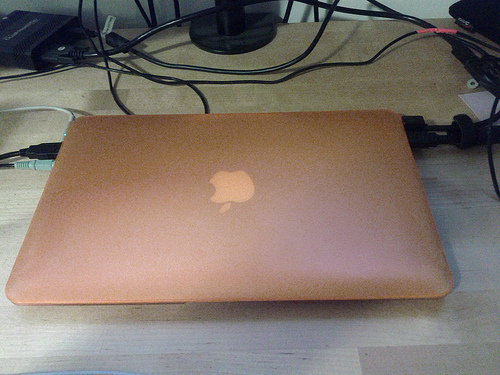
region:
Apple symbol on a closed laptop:
[203, 164, 259, 223]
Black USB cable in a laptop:
[18, 137, 73, 158]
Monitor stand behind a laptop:
[183, 0, 280, 55]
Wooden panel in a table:
[293, 317, 493, 373]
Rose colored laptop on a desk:
[4, 100, 456, 310]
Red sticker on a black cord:
[411, 22, 465, 39]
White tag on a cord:
[98, 14, 119, 39]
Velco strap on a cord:
[452, 112, 477, 150]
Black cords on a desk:
[142, 45, 359, 96]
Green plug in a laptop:
[13, 155, 61, 172]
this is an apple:
[199, 160, 261, 204]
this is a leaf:
[212, 197, 234, 216]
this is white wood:
[318, 330, 365, 355]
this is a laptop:
[3, 105, 476, 326]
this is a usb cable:
[11, 135, 70, 164]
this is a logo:
[206, 170, 265, 214]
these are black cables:
[126, 56, 251, 113]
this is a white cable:
[6, 95, 75, 134]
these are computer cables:
[403, 91, 498, 161]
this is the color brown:
[302, 204, 329, 233]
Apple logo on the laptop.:
[199, 150, 372, 240]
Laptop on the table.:
[38, 105, 440, 340]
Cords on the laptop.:
[383, 95, 498, 155]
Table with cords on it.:
[84, 47, 496, 306]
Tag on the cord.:
[85, 24, 128, 37]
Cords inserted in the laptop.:
[8, 109, 90, 191]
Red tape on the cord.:
[395, 13, 495, 50]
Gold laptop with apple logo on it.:
[44, 107, 299, 370]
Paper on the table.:
[408, 51, 498, 146]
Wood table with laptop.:
[45, 8, 460, 373]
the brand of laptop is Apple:
[0, 92, 470, 320]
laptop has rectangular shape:
[0, 101, 465, 312]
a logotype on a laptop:
[196, 157, 264, 221]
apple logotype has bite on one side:
[194, 163, 260, 220]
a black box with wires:
[5, 8, 95, 77]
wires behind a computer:
[87, 30, 427, 105]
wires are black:
[103, 44, 425, 96]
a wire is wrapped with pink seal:
[394, 16, 467, 51]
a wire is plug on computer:
[9, 146, 56, 176]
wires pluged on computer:
[7, 103, 95, 175]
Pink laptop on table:
[52, 110, 418, 336]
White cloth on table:
[225, 317, 385, 352]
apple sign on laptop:
[197, 151, 264, 224]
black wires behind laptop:
[88, 70, 219, 108]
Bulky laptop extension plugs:
[404, 107, 481, 163]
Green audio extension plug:
[5, 156, 55, 180]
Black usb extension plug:
[12, 135, 65, 157]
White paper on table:
[458, 88, 498, 117]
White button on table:
[463, 73, 479, 92]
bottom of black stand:
[169, 18, 298, 60]